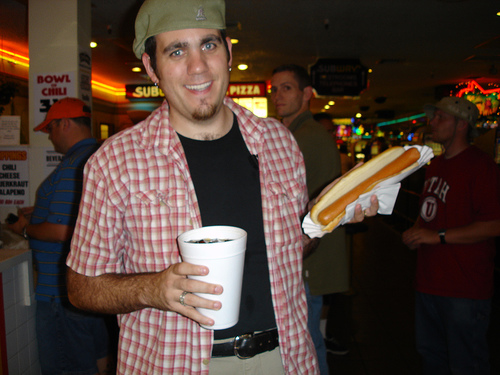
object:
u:
[142, 85, 151, 96]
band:
[178, 290, 195, 306]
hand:
[149, 261, 222, 326]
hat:
[133, 0, 228, 59]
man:
[66, 0, 381, 375]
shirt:
[64, 97, 322, 375]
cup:
[178, 225, 248, 329]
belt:
[211, 326, 278, 358]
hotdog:
[309, 147, 424, 231]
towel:
[298, 144, 436, 240]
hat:
[34, 96, 94, 130]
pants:
[199, 325, 319, 375]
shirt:
[413, 146, 498, 301]